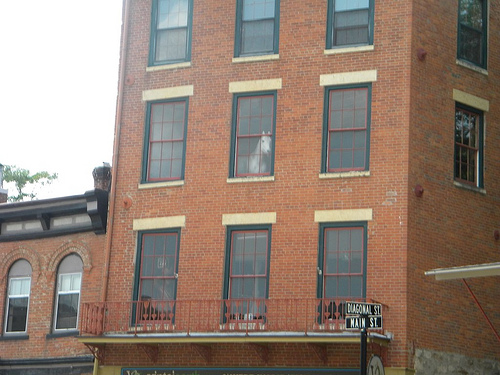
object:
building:
[0, 0, 499, 375]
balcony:
[80, 297, 390, 347]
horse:
[243, 130, 272, 173]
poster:
[414, 344, 499, 375]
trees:
[1, 164, 58, 201]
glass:
[236, 98, 272, 174]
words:
[347, 303, 383, 329]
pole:
[361, 329, 366, 374]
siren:
[418, 48, 427, 62]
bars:
[236, 94, 273, 177]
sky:
[4, 0, 106, 117]